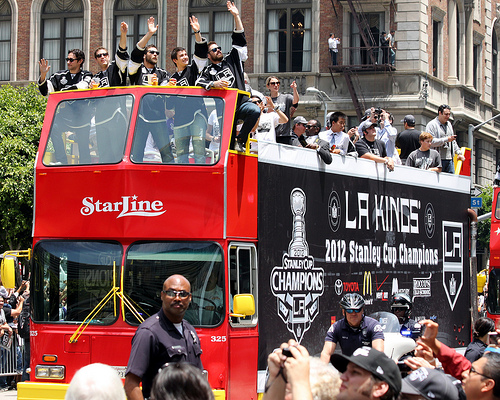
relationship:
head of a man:
[168, 45, 192, 73] [170, 15, 202, 80]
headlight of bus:
[33, 363, 67, 382] [33, 93, 471, 256]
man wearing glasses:
[157, 272, 192, 330] [163, 289, 192, 300]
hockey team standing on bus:
[29, 0, 252, 82] [33, 93, 471, 256]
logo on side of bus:
[268, 182, 326, 339] [33, 93, 471, 256]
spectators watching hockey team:
[285, 329, 495, 394] [29, 0, 252, 82]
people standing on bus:
[294, 86, 462, 175] [33, 93, 471, 256]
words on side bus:
[344, 188, 423, 242] [33, 93, 471, 256]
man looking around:
[170, 15, 202, 80] [250, 24, 253, 25]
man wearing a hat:
[400, 112, 417, 142] [401, 111, 415, 122]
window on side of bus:
[139, 93, 227, 170] [33, 93, 471, 256]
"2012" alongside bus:
[322, 236, 348, 264] [33, 93, 471, 256]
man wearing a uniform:
[157, 272, 192, 330] [133, 322, 207, 358]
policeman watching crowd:
[134, 268, 206, 349] [285, 329, 495, 394]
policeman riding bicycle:
[326, 289, 367, 339] [325, 355, 329, 361]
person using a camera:
[263, 333, 397, 395] [279, 345, 294, 361]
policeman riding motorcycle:
[390, 290, 413, 317] [384, 315, 407, 356]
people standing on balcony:
[377, 26, 396, 61] [328, 20, 404, 73]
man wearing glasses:
[60, 49, 84, 72] [66, 55, 78, 64]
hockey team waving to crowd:
[29, 0, 252, 82] [285, 329, 495, 394]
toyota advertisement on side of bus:
[333, 276, 358, 294] [33, 93, 471, 256]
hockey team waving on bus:
[29, 0, 252, 82] [33, 93, 471, 256]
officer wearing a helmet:
[326, 289, 367, 339] [340, 291, 369, 311]